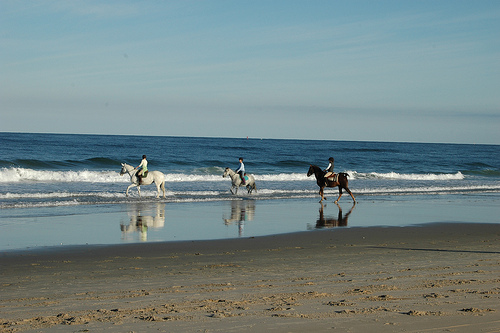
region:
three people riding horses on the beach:
[102, 151, 384, 236]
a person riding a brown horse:
[303, 155, 358, 210]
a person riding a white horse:
[118, 155, 171, 205]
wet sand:
[50, 255, 485, 330]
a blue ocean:
[36, 133, 476, 165]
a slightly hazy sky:
[37, 17, 457, 123]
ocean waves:
[19, 155, 106, 184]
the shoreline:
[27, 207, 299, 234]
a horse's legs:
[318, 187, 361, 205]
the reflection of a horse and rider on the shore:
[118, 203, 170, 248]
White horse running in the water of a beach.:
[118, 160, 168, 197]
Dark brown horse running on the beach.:
[305, 164, 357, 206]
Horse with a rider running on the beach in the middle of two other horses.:
[223, 167, 258, 194]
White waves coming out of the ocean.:
[16, 164, 63, 181]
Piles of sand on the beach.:
[330, 302, 360, 319]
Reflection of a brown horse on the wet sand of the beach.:
[306, 203, 356, 229]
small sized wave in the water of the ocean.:
[85, 153, 120, 167]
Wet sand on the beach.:
[432, 199, 464, 224]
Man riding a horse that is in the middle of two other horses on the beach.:
[235, 156, 249, 186]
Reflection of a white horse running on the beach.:
[116, 197, 167, 239]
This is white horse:
[116, 146, 175, 198]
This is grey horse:
[211, 152, 281, 202]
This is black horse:
[301, 141, 364, 212]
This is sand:
[112, 247, 462, 331]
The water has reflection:
[114, 167, 403, 265]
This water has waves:
[26, 138, 418, 224]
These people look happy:
[83, 140, 411, 230]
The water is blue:
[25, 131, 373, 281]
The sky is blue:
[11, 18, 498, 168]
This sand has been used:
[163, 215, 490, 320]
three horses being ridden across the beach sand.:
[41, 100, 452, 236]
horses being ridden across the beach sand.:
[40, 90, 435, 260]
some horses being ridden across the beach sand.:
[35, 55, 420, 255]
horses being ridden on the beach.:
[20, 70, 415, 245]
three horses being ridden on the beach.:
[56, 70, 406, 270]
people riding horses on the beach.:
[41, 119, 420, 279]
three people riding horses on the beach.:
[42, 110, 412, 255]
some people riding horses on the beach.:
[42, 68, 418, 248]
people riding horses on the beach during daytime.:
[39, 85, 439, 222]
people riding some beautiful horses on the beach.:
[62, 93, 410, 240]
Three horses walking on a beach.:
[104, 162, 378, 214]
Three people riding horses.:
[117, 150, 350, 175]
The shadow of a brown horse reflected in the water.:
[291, 192, 356, 233]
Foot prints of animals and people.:
[67, 266, 475, 321]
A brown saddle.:
[130, 168, 152, 185]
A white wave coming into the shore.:
[14, 164, 451, 184]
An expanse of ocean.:
[14, 126, 488, 177]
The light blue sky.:
[34, 43, 461, 133]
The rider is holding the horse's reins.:
[123, 163, 144, 173]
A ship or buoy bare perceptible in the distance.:
[231, 131, 271, 141]